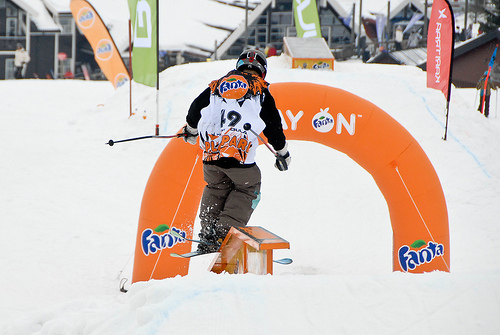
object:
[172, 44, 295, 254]
person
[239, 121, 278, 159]
ski pole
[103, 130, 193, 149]
ski pole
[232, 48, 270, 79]
helmet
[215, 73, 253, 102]
advertisement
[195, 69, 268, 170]
back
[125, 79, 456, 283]
inflatable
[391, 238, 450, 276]
logo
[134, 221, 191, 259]
logo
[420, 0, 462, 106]
banner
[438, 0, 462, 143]
pole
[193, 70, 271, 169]
vest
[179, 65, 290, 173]
jacket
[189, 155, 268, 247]
pants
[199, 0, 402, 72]
building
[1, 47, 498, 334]
snow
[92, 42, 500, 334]
slope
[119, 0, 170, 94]
sign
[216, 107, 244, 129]
number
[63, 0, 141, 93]
banner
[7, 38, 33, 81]
person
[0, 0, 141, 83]
chalet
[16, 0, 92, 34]
roof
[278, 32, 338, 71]
jump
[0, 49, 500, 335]
ground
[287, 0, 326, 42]
flag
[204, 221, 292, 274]
slide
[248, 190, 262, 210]
patch